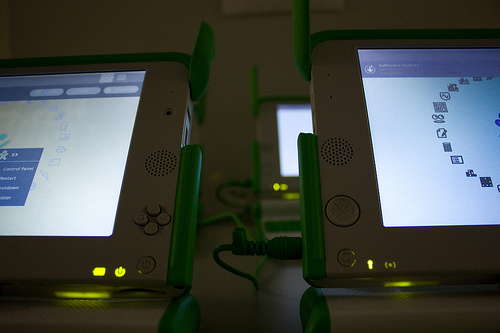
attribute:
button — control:
[144, 220, 157, 232]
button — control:
[132, 209, 148, 221]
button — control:
[146, 201, 161, 213]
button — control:
[155, 211, 172, 224]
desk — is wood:
[49, 180, 446, 332]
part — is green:
[166, 144, 205, 294]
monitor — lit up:
[4, 51, 211, 303]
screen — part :
[304, 27, 499, 287]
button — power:
[114, 259, 127, 284]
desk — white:
[159, 205, 374, 332]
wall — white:
[0, 1, 498, 256]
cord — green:
[217, 228, 299, 295]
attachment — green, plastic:
[285, 127, 336, 305]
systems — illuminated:
[1, 30, 498, 291]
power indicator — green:
[111, 265, 128, 280]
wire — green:
[212, 230, 307, 304]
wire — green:
[199, 176, 257, 241]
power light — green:
[381, 259, 399, 269]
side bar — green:
[295, 127, 325, 285]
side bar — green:
[291, 0, 311, 87]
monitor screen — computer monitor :
[353, 49, 498, 227]